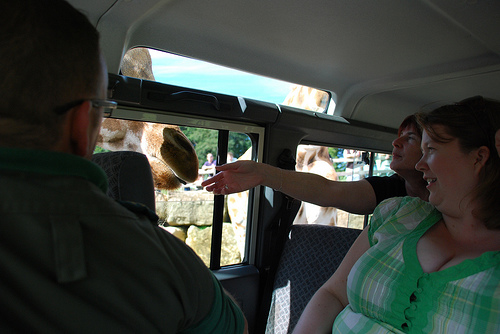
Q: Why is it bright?
A: It is sunny.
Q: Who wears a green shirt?
A: The woman.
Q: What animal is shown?
A: A giraffe.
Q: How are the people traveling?
A: In a vehicle.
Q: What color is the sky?
A: Blue.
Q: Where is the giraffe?
A: Outside the window.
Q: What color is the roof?
A: White.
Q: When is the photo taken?
A: Daytime.